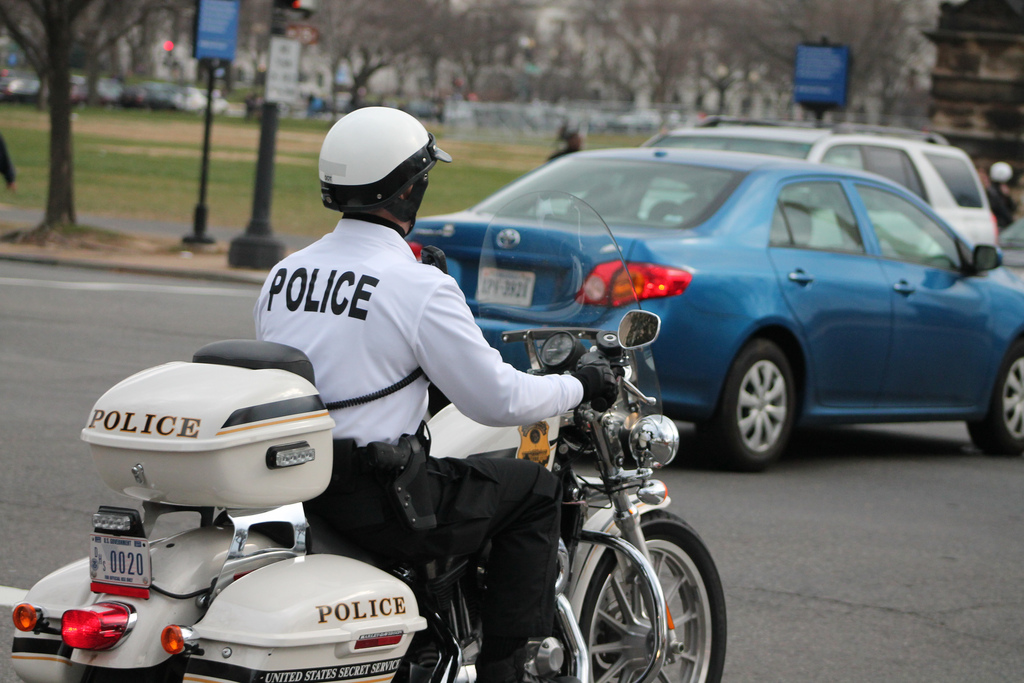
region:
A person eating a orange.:
[632, 365, 740, 482]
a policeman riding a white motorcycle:
[17, 107, 720, 677]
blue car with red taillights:
[402, 144, 1022, 473]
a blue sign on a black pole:
[182, 4, 239, 242]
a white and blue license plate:
[84, 535, 152, 584]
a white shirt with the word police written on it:
[251, 219, 581, 445]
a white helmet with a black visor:
[315, 107, 452, 216]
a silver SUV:
[640, 128, 999, 247]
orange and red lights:
[10, 602, 187, 650]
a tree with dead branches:
[2, 0, 179, 231]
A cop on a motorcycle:
[258, 99, 616, 673]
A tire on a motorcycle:
[577, 499, 733, 677]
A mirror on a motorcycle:
[609, 307, 664, 346]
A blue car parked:
[416, 139, 1021, 465]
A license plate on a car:
[470, 259, 544, 310]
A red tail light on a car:
[578, 246, 693, 310]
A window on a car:
[766, 162, 871, 257]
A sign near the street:
[173, 4, 235, 260]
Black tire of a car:
[718, 330, 799, 467]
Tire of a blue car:
[705, 327, 797, 470]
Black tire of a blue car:
[697, 332, 793, 472]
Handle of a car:
[782, 264, 817, 288]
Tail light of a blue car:
[579, 251, 697, 312]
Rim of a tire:
[743, 364, 783, 438]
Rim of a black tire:
[738, 356, 783, 448]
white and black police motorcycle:
[53, 285, 762, 678]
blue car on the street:
[432, 142, 1022, 453]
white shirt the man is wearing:
[246, 238, 560, 444]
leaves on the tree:
[93, 22, 116, 83]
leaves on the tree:
[743, 28, 769, 86]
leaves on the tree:
[672, 1, 733, 74]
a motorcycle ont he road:
[210, 192, 757, 677]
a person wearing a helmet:
[313, 83, 397, 240]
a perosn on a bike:
[131, 259, 373, 583]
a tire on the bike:
[564, 420, 765, 677]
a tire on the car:
[705, 350, 801, 449]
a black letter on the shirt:
[359, 274, 391, 338]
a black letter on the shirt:
[330, 247, 356, 308]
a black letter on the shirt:
[313, 253, 353, 326]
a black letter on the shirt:
[295, 247, 327, 302]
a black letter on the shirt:
[257, 271, 297, 317]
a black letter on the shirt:
[76, 391, 146, 467]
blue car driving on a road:
[399, 143, 1022, 469]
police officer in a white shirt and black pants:
[262, 101, 617, 680]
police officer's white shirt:
[260, 218, 586, 447]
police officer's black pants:
[320, 437, 564, 665]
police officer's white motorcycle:
[15, 311, 731, 679]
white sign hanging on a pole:
[270, 28, 303, 104]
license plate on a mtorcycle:
[85, 535, 158, 584]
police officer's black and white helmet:
[324, 96, 451, 217]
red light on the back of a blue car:
[590, 253, 692, 311]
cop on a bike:
[48, 54, 756, 674]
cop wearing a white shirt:
[221, 141, 601, 464]